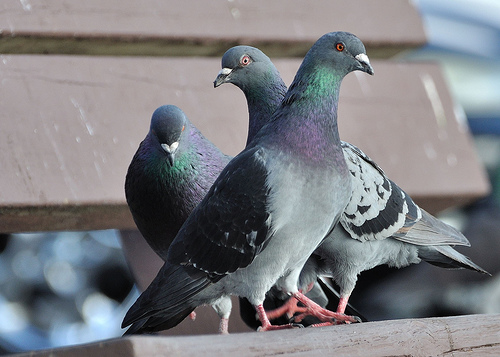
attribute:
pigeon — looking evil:
[126, 105, 202, 209]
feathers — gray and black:
[343, 153, 403, 236]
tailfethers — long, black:
[120, 260, 217, 337]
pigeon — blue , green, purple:
[122, 102, 239, 269]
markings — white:
[349, 160, 393, 227]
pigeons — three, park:
[95, 14, 499, 344]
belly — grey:
[281, 164, 349, 274]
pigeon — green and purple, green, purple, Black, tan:
[125, 29, 377, 334]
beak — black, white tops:
[355, 50, 375, 74]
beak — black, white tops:
[214, 60, 238, 90]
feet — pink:
[293, 294, 360, 323]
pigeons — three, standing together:
[128, 32, 420, 316]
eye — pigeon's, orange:
[334, 42, 344, 52]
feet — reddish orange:
[256, 303, 303, 334]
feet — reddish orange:
[286, 285, 362, 321]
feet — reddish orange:
[306, 292, 353, 327]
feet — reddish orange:
[258, 294, 311, 320]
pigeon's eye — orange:
[332, 37, 346, 54]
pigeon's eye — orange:
[239, 52, 251, 65]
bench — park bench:
[55, 11, 463, 346]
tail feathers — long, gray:
[399, 191, 492, 279]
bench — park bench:
[61, 243, 393, 355]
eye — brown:
[335, 42, 344, 51]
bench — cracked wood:
[149, 33, 479, 267]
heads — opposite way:
[201, 26, 383, 100]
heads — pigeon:
[96, 23, 383, 186]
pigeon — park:
[193, 65, 371, 233]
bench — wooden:
[286, 316, 356, 355]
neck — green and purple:
[260, 51, 346, 172]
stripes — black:
[334, 149, 402, 236]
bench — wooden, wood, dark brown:
[4, 4, 484, 352]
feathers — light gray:
[270, 167, 351, 274]